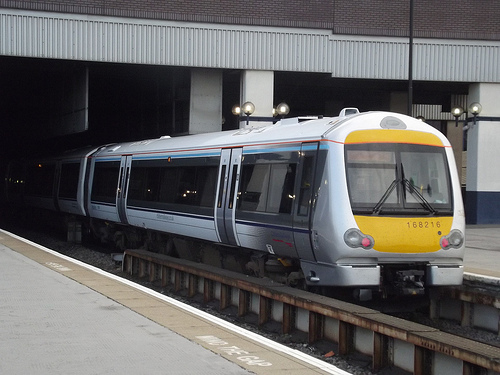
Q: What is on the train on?
A: Track.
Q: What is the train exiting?
A: Building.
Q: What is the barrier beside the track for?
A: Warning.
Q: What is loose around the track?
A: Gravel.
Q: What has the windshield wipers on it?
A: Windshield.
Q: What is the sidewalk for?
A: Passengers to wait.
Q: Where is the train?
A: Crossing the tunnel.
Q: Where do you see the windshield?
A: Front of the train.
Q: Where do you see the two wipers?
A: Windshield.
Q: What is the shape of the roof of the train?
A: Concave.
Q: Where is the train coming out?
A: Tunnel.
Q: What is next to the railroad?
A: Platform.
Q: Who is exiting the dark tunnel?
A: Train.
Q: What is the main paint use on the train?
A: Gray.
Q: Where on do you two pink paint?
A: Front of the train.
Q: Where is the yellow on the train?
A: Front.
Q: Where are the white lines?
A: Edge of the platforms.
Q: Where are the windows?
A: On the train.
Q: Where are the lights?
A: Attached to the black metal poles.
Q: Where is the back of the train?
A: Inside the building.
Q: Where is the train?
A: On tracks.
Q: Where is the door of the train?
A: On the side.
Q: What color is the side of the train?
A: White.